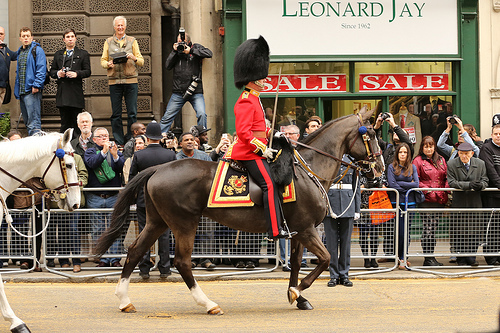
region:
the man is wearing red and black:
[228, 33, 293, 253]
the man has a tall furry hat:
[232, 29, 306, 266]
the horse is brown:
[101, 139, 431, 270]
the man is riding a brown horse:
[125, 56, 389, 313]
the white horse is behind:
[7, 107, 79, 273]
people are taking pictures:
[46, 35, 220, 167]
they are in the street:
[28, 21, 475, 304]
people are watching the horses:
[40, 99, 485, 196]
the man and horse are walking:
[110, 34, 392, 317]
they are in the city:
[19, 4, 496, 331]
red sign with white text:
[360, 72, 449, 91]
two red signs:
[265, 74, 451, 90]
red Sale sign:
[360, 74, 452, 90]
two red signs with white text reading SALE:
[257, 76, 450, 90]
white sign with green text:
[246, 0, 451, 53]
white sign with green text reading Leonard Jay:
[248, 0, 456, 57]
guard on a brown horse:
[91, 33, 388, 311]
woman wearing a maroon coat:
[416, 134, 449, 271]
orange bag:
[369, 187, 393, 223]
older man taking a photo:
[91, 126, 128, 268]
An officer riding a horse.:
[225, 32, 296, 241]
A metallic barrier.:
[409, 207, 499, 256]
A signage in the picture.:
[270, 5, 462, 95]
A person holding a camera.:
[87, 127, 123, 184]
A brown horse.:
[94, 105, 392, 314]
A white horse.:
[0, 135, 81, 331]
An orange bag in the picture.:
[365, 187, 400, 225]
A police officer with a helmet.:
[130, 123, 172, 171]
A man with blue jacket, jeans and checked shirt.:
[11, 24, 46, 132]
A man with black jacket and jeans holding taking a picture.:
[161, 21, 206, 136]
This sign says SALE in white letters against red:
[359, 65, 443, 115]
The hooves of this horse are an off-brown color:
[183, 280, 226, 322]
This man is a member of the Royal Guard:
[222, 15, 327, 267]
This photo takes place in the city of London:
[82, 19, 434, 319]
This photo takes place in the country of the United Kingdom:
[103, 17, 440, 304]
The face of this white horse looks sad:
[35, 118, 95, 220]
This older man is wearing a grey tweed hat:
[453, 142, 483, 204]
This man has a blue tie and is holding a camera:
[61, 24, 91, 66]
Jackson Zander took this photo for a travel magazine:
[75, 32, 377, 267]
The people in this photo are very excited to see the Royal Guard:
[78, 27, 387, 325]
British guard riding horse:
[106, 23, 409, 308]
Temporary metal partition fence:
[2, 173, 489, 285]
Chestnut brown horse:
[77, 103, 408, 314]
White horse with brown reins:
[1, 122, 84, 314]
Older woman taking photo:
[431, 107, 492, 187]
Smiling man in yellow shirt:
[91, 8, 171, 135]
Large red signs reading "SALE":
[244, 57, 474, 112]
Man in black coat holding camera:
[49, 20, 94, 115]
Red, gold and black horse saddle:
[209, 125, 306, 222]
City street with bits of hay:
[0, 272, 484, 332]